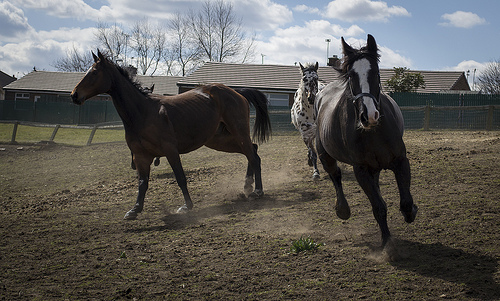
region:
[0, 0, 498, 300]
The horses are outside.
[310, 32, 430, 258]
The horse is brown with a white spot on the face.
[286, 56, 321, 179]
The horse is white with black dots.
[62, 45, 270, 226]
The horse is brown.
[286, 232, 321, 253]
A small patch of grass.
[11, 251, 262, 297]
Dirt on the ground.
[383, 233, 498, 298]
The shadow of a horse.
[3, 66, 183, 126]
A building behind the horses.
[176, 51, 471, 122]
Another building next to it.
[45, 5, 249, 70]
Trees without any leaves.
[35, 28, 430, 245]
three horses on a field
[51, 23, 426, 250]
three horses running together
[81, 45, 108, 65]
perky ears of brown horse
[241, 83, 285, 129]
black tail of brown horse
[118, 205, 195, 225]
white hooves of horse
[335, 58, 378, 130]
white and brown head of horse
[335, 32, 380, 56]
brown perky ears of horse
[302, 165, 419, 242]
short brown legs of horse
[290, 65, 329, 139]
white and black horse running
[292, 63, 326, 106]
white and black head of horse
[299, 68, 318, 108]
Horse in the background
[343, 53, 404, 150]
Horse in the front right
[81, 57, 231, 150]
Horse in the front left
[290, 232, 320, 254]
Patch of green grass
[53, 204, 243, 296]
Brown dirt on the ground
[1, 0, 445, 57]
White clouds in the sky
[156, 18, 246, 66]
Trees without leaves in the background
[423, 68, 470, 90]
Top of a farm house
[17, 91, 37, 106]
Farm house window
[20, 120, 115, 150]
Ranch gate made of iron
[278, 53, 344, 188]
The horse is running.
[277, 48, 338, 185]
The horse is black and white.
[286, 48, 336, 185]
The horse is spotted.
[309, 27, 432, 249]
The horse is brown and white.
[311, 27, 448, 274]
The horse is running.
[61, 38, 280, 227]
The horse is black, brown and white.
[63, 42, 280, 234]
The horse is standing.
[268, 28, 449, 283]
The horse is stirring up dust.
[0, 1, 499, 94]
White fluffy clouds fill the blue sky.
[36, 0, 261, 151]
The trees are bare.